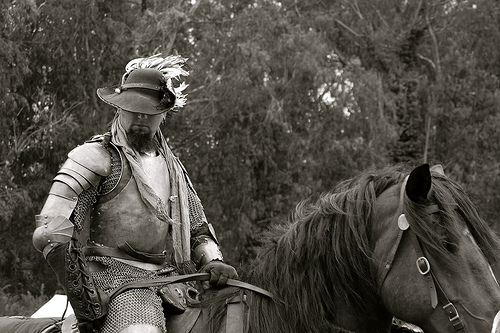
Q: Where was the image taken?
A: It was taken at the forest.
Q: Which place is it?
A: It is a forest.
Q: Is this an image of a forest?
A: Yes, it is showing a forest.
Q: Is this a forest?
A: Yes, it is a forest.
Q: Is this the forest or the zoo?
A: It is the forest.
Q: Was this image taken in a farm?
A: No, the picture was taken in a forest.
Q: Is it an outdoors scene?
A: Yes, it is outdoors.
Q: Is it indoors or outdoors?
A: It is outdoors.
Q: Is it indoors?
A: No, it is outdoors.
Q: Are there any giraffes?
A: No, there are no giraffes.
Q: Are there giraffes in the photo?
A: No, there are no giraffes.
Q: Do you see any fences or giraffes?
A: No, there are no giraffes or fences.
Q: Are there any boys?
A: No, there are no boys.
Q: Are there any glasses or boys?
A: No, there are no boys or glasses.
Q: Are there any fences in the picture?
A: No, there are no fences.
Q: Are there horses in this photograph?
A: Yes, there is a horse.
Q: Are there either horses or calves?
A: Yes, there is a horse.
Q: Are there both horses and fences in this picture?
A: No, there is a horse but no fences.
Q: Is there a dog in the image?
A: No, there are no dogs.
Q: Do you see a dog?
A: No, there are no dogs.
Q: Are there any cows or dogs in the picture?
A: No, there are no dogs or cows.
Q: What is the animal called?
A: The animal is a horse.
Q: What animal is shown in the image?
A: The animal is a horse.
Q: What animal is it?
A: The animal is a horse.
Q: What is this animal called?
A: This is a horse.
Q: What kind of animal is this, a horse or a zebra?
A: This is a horse.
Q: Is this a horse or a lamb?
A: This is a horse.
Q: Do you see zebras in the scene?
A: No, there are no zebras.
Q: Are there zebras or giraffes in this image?
A: No, there are no zebras or giraffes.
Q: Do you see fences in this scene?
A: No, there are no fences.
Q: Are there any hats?
A: Yes, there is a hat.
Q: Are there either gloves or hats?
A: Yes, there is a hat.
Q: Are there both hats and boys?
A: No, there is a hat but no boys.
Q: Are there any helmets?
A: No, there are no helmets.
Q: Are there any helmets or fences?
A: No, there are no helmets or fences.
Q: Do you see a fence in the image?
A: No, there are no fences.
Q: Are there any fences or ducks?
A: No, there are no fences or ducks.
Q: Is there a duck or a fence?
A: No, there are no fences or ducks.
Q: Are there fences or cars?
A: No, there are no fences or cars.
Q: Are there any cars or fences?
A: No, there are no fences or cars.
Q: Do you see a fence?
A: No, there are no fences.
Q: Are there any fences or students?
A: No, there are no fences or students.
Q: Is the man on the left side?
A: Yes, the man is on the left of the image.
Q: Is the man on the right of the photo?
A: No, the man is on the left of the image.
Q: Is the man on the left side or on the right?
A: The man is on the left of the image.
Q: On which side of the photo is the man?
A: The man is on the left of the image.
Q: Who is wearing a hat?
A: The man is wearing a hat.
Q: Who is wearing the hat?
A: The man is wearing a hat.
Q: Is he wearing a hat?
A: Yes, the man is wearing a hat.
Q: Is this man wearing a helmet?
A: No, the man is wearing a hat.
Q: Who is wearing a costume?
A: The man is wearing a costume.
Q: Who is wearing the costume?
A: The man is wearing a costume.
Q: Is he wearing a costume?
A: Yes, the man is wearing a costume.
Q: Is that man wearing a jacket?
A: No, the man is wearing a costume.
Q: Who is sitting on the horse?
A: The man is sitting on the horse.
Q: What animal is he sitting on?
A: The man is sitting on the horse.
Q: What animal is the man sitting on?
A: The man is sitting on the horse.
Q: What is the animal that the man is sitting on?
A: The animal is a horse.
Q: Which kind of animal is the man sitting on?
A: The man is sitting on the horse.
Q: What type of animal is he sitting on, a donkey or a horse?
A: The man is sitting on a horse.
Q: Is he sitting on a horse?
A: Yes, the man is sitting on a horse.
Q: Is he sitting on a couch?
A: No, the man is sitting on a horse.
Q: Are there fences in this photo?
A: No, there are no fences.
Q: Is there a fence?
A: No, there are no fences.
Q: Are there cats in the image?
A: No, there are no cats.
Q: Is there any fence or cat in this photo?
A: No, there are no cats or fences.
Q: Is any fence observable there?
A: No, there are no fences.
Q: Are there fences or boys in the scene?
A: No, there are no fences or boys.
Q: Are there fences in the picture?
A: No, there are no fences.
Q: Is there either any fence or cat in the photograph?
A: No, there are no fences or cats.